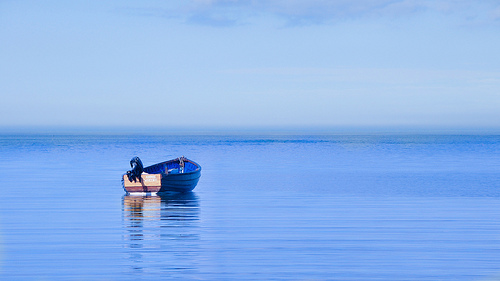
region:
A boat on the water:
[123, 156, 200, 196]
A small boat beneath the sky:
[124, 155, 200, 197]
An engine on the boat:
[128, 157, 144, 180]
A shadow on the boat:
[136, 175, 147, 190]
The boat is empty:
[123, 155, 200, 195]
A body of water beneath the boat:
[4, 130, 499, 278]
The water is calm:
[4, 135, 499, 279]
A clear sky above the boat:
[1, 0, 498, 130]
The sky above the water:
[1, 0, 498, 131]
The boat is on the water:
[124, 154, 199, 196]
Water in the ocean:
[277, 155, 379, 229]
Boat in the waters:
[112, 147, 204, 200]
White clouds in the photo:
[221, 42, 348, 108]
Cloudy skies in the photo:
[198, 26, 312, 93]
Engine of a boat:
[122, 149, 144, 179]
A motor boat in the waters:
[110, 93, 215, 202]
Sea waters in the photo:
[285, 170, 386, 242]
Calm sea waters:
[215, 127, 347, 179]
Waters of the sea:
[287, 132, 412, 224]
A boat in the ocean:
[110, 134, 210, 207]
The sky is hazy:
[2, 1, 497, 133]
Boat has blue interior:
[144, 159, 195, 174]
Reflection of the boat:
[119, 191, 199, 268]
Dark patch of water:
[250, 169, 499, 195]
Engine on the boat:
[127, 156, 142, 178]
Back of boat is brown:
[124, 173, 160, 189]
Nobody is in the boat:
[122, 156, 199, 196]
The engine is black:
[127, 156, 142, 181]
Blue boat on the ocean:
[106, 128, 211, 205]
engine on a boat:
[119, 150, 153, 190]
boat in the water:
[111, 129, 224, 209]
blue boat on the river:
[113, 140, 216, 205]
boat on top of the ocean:
[99, 126, 206, 204]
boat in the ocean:
[101, 123, 211, 213]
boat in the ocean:
[131, 151, 212, 206]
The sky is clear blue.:
[7, 6, 491, 115]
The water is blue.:
[4, 131, 496, 275]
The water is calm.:
[0, 127, 492, 274]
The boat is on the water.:
[93, 133, 202, 220]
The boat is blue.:
[114, 133, 224, 225]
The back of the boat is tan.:
[120, 163, 162, 198]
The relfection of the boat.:
[118, 185, 210, 223]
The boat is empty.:
[105, 149, 233, 221]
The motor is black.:
[122, 151, 148, 179]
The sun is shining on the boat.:
[7, 14, 486, 278]